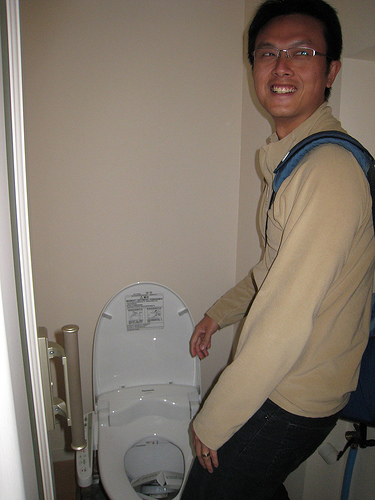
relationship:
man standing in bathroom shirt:
[160, 1, 373, 498] [193, 101, 375, 451]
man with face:
[160, 1, 373, 498] [248, 15, 321, 118]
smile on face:
[269, 80, 299, 94] [248, 15, 321, 118]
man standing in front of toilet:
[160, 1, 373, 498] [87, 283, 206, 492]